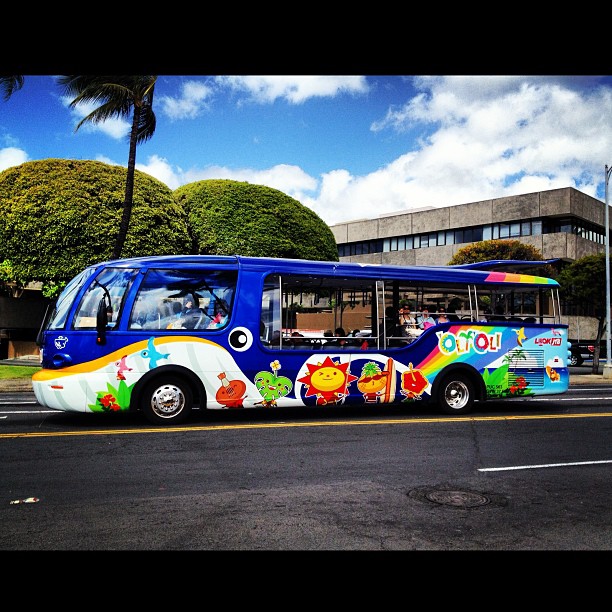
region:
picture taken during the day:
[9, 141, 596, 578]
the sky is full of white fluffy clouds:
[262, 95, 574, 199]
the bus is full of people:
[42, 249, 571, 409]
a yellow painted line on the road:
[71, 401, 601, 425]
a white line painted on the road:
[462, 465, 606, 475]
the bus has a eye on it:
[231, 325, 250, 348]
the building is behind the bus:
[336, 212, 593, 296]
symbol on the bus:
[136, 350, 177, 374]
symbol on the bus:
[91, 378, 126, 415]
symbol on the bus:
[217, 371, 240, 406]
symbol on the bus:
[250, 355, 292, 410]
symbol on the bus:
[306, 355, 352, 396]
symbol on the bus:
[347, 350, 393, 396]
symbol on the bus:
[391, 361, 424, 402]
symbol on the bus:
[434, 333, 509, 362]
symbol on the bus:
[549, 357, 562, 377]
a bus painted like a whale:
[38, 252, 574, 415]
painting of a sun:
[304, 357, 353, 402]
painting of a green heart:
[253, 368, 295, 406]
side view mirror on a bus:
[91, 295, 113, 347]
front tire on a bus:
[140, 372, 183, 416]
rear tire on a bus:
[433, 369, 465, 409]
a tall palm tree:
[68, 80, 157, 253]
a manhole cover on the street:
[424, 484, 493, 515]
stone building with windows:
[335, 184, 611, 267]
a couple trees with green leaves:
[6, 159, 345, 294]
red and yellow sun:
[301, 355, 355, 397]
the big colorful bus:
[61, 236, 568, 436]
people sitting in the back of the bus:
[387, 294, 546, 332]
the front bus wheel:
[145, 382, 195, 423]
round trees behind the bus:
[16, 155, 327, 318]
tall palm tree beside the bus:
[63, 72, 160, 311]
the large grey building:
[334, 182, 600, 402]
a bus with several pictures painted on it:
[30, 246, 579, 411]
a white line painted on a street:
[466, 442, 610, 484]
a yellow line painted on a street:
[62, 403, 530, 432]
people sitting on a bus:
[290, 323, 373, 345]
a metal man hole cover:
[423, 480, 483, 512]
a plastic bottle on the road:
[7, 492, 37, 512]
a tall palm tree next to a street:
[83, 75, 165, 270]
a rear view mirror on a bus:
[86, 271, 114, 349]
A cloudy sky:
[0, 146, 605, 242]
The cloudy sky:
[3, 148, 609, 219]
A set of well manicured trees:
[4, 153, 359, 314]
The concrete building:
[332, 179, 603, 316]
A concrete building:
[333, 201, 610, 273]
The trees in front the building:
[445, 227, 598, 331]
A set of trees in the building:
[453, 235, 607, 333]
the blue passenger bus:
[34, 233, 586, 452]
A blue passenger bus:
[33, 243, 586, 441]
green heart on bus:
[244, 356, 295, 410]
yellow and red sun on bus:
[297, 352, 355, 402]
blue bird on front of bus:
[142, 336, 176, 370]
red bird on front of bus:
[110, 349, 136, 382]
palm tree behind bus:
[67, 78, 164, 259]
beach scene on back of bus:
[482, 317, 566, 405]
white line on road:
[469, 447, 608, 474]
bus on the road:
[9, 200, 600, 541]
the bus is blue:
[45, 212, 555, 441]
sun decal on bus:
[279, 354, 361, 420]